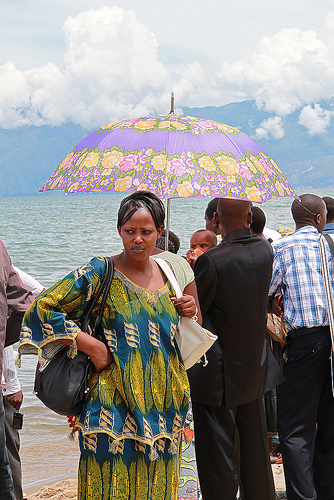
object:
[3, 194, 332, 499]
water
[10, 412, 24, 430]
camera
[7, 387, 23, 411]
hand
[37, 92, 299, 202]
umbrella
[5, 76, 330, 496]
event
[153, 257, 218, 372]
purse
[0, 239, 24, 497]
people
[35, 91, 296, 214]
colored umbrella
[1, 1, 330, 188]
sky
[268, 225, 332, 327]
shirt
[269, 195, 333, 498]
man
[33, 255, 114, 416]
handbag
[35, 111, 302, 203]
umbrella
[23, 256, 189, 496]
dress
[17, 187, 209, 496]
woman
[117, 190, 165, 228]
black hair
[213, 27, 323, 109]
two dogs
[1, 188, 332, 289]
ocean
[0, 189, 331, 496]
crowd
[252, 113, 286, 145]
cloud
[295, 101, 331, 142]
cloud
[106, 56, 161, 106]
wall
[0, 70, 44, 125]
cloud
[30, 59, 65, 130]
cloud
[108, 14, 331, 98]
cloud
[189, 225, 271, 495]
suit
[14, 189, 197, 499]
she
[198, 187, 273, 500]
people